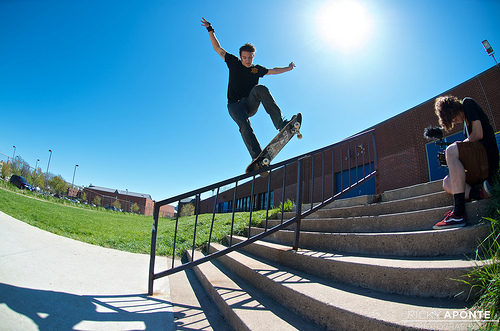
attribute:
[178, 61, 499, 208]
building — brick 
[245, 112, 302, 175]
skate board — black , white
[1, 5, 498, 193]
blue sky — clear , bright blue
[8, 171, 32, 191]
vehicle — black 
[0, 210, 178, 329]
sidewalk — cement 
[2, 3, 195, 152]
sky — clear, blue